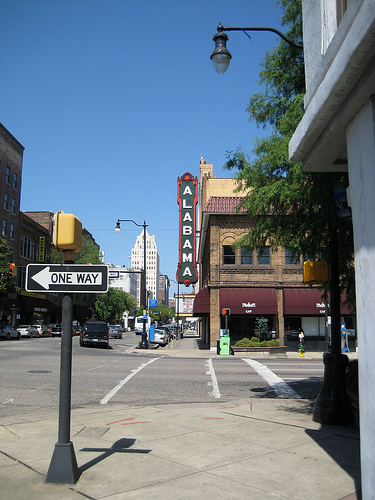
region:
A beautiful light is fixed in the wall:
[205, 18, 303, 75]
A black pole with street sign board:
[22, 262, 113, 484]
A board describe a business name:
[176, 173, 202, 284]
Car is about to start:
[81, 321, 119, 351]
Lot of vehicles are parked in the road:
[147, 316, 177, 354]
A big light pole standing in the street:
[113, 218, 152, 348]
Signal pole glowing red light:
[218, 303, 243, 375]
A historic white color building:
[132, 229, 156, 342]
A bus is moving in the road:
[135, 308, 152, 338]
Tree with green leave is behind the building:
[257, 120, 353, 444]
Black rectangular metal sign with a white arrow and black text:
[24, 262, 106, 289]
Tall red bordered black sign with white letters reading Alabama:
[172, 167, 205, 287]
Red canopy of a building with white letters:
[220, 286, 278, 315]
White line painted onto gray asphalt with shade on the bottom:
[239, 352, 301, 405]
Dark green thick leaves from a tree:
[235, 145, 313, 239]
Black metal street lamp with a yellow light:
[110, 217, 152, 259]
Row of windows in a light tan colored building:
[215, 230, 276, 271]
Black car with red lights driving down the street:
[75, 313, 119, 353]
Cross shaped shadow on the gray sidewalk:
[75, 426, 152, 472]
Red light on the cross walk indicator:
[216, 303, 230, 318]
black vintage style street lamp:
[195, 14, 302, 90]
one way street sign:
[19, 253, 113, 484]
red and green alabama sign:
[166, 163, 203, 303]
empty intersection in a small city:
[4, 230, 232, 413]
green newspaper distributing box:
[210, 326, 237, 357]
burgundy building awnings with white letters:
[189, 284, 351, 326]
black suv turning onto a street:
[75, 316, 115, 357]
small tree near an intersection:
[228, 131, 358, 429]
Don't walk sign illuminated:
[215, 302, 241, 328]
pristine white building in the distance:
[104, 213, 165, 314]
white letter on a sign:
[180, 182, 196, 197]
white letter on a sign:
[181, 195, 194, 211]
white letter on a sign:
[182, 209, 195, 224]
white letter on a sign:
[180, 223, 194, 237]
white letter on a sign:
[182, 235, 196, 248]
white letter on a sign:
[181, 249, 194, 261]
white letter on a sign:
[182, 261, 194, 278]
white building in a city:
[131, 227, 161, 297]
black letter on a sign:
[48, 270, 57, 285]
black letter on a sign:
[56, 269, 67, 284]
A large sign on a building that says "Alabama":
[165, 148, 205, 300]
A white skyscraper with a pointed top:
[126, 214, 161, 309]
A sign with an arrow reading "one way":
[14, 253, 131, 295]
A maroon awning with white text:
[189, 284, 349, 316]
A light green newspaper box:
[208, 326, 247, 364]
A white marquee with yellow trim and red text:
[166, 287, 214, 326]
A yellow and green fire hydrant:
[298, 340, 316, 366]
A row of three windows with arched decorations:
[215, 231, 274, 276]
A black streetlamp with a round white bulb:
[111, 214, 160, 355]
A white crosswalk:
[103, 344, 236, 432]